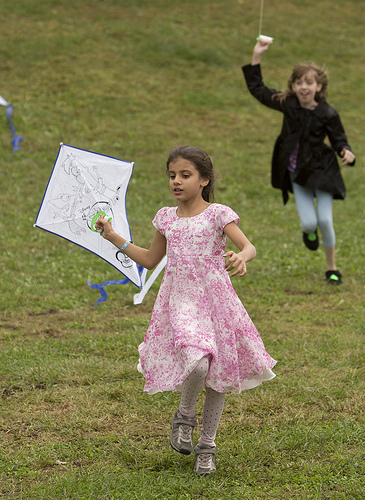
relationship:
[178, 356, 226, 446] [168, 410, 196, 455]
socks and shoe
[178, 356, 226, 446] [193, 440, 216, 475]
socks and shoe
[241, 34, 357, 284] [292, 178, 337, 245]
child wearing jeans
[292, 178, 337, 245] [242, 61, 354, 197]
jeans and coat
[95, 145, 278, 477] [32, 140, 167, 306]
child holding kite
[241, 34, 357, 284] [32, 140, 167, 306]
child holding kite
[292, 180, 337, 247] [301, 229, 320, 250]
jeans and shoe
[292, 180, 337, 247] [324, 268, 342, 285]
jeans and shoe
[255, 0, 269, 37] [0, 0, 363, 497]
kite in front of grass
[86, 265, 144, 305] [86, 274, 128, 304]
blue tail on blue tail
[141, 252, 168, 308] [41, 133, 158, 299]
streamer in kite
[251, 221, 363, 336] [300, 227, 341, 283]
grass in shoes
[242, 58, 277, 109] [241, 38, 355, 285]
arm of child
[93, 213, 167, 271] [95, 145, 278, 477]
arm on child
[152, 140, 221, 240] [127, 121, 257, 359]
head of girl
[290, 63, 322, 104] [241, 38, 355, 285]
head of child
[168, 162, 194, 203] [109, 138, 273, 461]
face of girl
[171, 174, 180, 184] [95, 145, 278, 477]
nose of child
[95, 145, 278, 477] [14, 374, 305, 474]
child running field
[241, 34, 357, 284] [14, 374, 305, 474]
child running field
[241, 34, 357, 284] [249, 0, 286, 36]
child running with kite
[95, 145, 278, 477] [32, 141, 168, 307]
child running with girl kite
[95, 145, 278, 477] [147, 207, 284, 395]
child in dress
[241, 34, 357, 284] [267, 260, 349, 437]
child running in yard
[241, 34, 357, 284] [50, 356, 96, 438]
child on grass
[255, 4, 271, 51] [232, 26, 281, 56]
string in hand